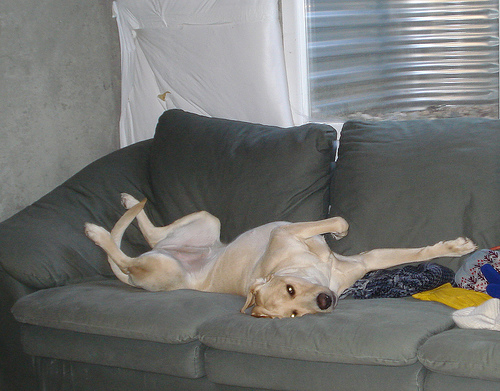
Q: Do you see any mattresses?
A: No, there are no mattresses.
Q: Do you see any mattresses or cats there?
A: No, there are no mattresses or cats.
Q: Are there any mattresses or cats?
A: No, there are no mattresses or cats.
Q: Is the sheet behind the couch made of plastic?
A: Yes, the bed sheet is made of plastic.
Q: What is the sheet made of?
A: The bed sheet is made of plastic.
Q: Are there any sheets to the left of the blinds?
A: Yes, there is a sheet to the left of the blinds.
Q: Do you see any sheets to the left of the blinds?
A: Yes, there is a sheet to the left of the blinds.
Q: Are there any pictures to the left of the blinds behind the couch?
A: No, there is a sheet to the left of the blinds.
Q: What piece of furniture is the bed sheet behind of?
A: The bed sheet is behind the couch.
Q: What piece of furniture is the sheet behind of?
A: The bed sheet is behind the couch.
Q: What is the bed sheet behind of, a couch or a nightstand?
A: The bed sheet is behind a couch.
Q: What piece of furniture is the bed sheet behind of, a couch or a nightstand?
A: The bed sheet is behind a couch.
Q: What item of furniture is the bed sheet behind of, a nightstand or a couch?
A: The bed sheet is behind a couch.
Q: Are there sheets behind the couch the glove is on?
A: Yes, there is a sheet behind the couch.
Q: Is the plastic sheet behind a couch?
A: Yes, the sheet is behind a couch.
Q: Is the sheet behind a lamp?
A: No, the sheet is behind a couch.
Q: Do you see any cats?
A: No, there are no cats.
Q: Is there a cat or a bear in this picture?
A: No, there are no cats or bears.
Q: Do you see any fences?
A: No, there are no fences.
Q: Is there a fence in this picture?
A: No, there are no fences.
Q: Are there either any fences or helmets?
A: No, there are no fences or helmets.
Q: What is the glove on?
A: The glove is on the couch.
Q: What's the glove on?
A: The glove is on the couch.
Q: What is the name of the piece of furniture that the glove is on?
A: The piece of furniture is a couch.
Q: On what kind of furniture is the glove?
A: The glove is on the couch.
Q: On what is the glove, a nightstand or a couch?
A: The glove is on a couch.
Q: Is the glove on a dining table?
A: No, the glove is on the couch.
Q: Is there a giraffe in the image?
A: No, there are no giraffes.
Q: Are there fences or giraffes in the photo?
A: No, there are no giraffes or fences.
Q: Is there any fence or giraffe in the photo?
A: No, there are no giraffes or fences.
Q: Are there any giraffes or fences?
A: No, there are no giraffes or fences.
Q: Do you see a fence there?
A: No, there are no fences.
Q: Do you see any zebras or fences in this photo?
A: No, there are no fences or zebras.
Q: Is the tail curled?
A: Yes, the tail is curled.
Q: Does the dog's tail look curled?
A: Yes, the tail is curled.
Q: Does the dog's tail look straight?
A: No, the tail is curled.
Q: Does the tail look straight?
A: No, the tail is curled.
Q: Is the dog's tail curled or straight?
A: The tail is curled.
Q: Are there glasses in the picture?
A: No, there are no glasses.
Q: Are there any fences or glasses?
A: No, there are no glasses or fences.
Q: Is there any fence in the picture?
A: No, there are no fences.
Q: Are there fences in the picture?
A: No, there are no fences.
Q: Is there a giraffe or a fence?
A: No, there are no fences or giraffes.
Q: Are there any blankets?
A: Yes, there is a blanket.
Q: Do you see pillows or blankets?
A: Yes, there is a blanket.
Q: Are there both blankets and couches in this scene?
A: Yes, there are both a blanket and a couch.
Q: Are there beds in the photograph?
A: No, there are no beds.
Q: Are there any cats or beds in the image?
A: No, there are no beds or cats.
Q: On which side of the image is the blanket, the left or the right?
A: The blanket is on the right of the image.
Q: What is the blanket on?
A: The blanket is on the couch.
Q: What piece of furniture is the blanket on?
A: The blanket is on the couch.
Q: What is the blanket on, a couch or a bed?
A: The blanket is on a couch.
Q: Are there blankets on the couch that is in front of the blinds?
A: Yes, there is a blanket on the couch.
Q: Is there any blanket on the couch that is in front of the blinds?
A: Yes, there is a blanket on the couch.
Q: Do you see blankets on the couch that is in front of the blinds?
A: Yes, there is a blanket on the couch.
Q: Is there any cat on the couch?
A: No, there is a blanket on the couch.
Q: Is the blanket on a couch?
A: Yes, the blanket is on a couch.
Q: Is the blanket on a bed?
A: No, the blanket is on a couch.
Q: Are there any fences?
A: No, there are no fences.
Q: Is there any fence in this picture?
A: No, there are no fences.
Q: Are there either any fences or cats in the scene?
A: No, there are no fences or cats.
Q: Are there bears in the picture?
A: No, there are no bears.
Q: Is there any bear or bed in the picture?
A: No, there are no bears or beds.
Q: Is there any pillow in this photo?
A: Yes, there are pillows.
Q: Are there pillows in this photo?
A: Yes, there are pillows.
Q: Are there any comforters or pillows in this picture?
A: Yes, there are pillows.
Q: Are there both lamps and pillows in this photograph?
A: No, there are pillows but no lamps.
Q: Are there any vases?
A: No, there are no vases.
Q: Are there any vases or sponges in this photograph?
A: No, there are no vases or sponges.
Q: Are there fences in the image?
A: No, there are no fences.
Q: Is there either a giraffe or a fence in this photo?
A: No, there are no fences or giraffes.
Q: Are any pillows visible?
A: Yes, there is a pillow.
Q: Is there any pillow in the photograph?
A: Yes, there is a pillow.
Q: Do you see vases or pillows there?
A: Yes, there is a pillow.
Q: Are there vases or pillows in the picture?
A: Yes, there is a pillow.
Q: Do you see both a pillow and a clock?
A: No, there is a pillow but no clocks.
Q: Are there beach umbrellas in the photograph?
A: No, there are no beach umbrellas.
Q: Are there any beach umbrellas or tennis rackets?
A: No, there are no beach umbrellas or tennis rackets.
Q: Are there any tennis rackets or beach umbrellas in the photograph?
A: No, there are no beach umbrellas or tennis rackets.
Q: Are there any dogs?
A: Yes, there is a dog.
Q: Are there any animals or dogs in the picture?
A: Yes, there is a dog.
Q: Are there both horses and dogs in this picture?
A: No, there is a dog but no horses.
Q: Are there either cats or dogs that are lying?
A: Yes, the dog is lying.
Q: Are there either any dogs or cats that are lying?
A: Yes, the dog is lying.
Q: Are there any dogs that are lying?
A: Yes, there is a dog that is lying.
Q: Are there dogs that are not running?
A: Yes, there is a dog that is lying.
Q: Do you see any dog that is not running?
A: Yes, there is a dog that is lying .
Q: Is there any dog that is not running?
A: Yes, there is a dog that is lying.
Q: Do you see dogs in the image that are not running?
A: Yes, there is a dog that is lying .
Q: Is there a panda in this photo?
A: No, there are no pandas.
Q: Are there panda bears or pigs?
A: No, there are no panda bears or pigs.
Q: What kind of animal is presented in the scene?
A: The animal is a dog.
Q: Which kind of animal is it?
A: The animal is a dog.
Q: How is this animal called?
A: This is a dog.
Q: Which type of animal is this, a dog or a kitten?
A: This is a dog.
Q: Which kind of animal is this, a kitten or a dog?
A: This is a dog.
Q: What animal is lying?
A: The animal is a dog.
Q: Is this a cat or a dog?
A: This is a dog.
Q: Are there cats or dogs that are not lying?
A: No, there is a dog but it is lying.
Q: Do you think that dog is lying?
A: Yes, the dog is lying.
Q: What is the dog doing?
A: The dog is lying.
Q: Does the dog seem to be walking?
A: No, the dog is lying.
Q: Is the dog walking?
A: No, the dog is lying.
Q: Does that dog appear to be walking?
A: No, the dog is lying.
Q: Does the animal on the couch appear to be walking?
A: No, the dog is lying.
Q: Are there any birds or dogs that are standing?
A: No, there is a dog but it is lying.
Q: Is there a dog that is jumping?
A: No, there is a dog but it is lying.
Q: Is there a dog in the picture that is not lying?
A: No, there is a dog but it is lying.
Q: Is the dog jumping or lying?
A: The dog is lying.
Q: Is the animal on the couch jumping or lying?
A: The dog is lying.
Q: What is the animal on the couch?
A: The animal is a dog.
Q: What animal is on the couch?
A: The animal is a dog.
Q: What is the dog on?
A: The dog is on the couch.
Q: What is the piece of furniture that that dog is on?
A: The piece of furniture is a couch.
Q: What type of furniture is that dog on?
A: The dog is on the couch.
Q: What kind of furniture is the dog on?
A: The dog is on the couch.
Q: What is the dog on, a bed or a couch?
A: The dog is on a couch.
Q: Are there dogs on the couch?
A: Yes, there is a dog on the couch.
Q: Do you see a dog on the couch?
A: Yes, there is a dog on the couch.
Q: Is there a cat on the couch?
A: No, there is a dog on the couch.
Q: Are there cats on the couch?
A: No, there is a dog on the couch.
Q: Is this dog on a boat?
A: No, the dog is on the couch.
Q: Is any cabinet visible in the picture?
A: No, there are no cabinets.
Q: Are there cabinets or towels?
A: No, there are no cabinets or towels.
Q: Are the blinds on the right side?
A: Yes, the blinds are on the right of the image.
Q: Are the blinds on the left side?
A: No, the blinds are on the right of the image.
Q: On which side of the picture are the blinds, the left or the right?
A: The blinds are on the right of the image.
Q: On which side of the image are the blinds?
A: The blinds are on the right of the image.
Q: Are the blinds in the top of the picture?
A: Yes, the blinds are in the top of the image.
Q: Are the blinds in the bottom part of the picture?
A: No, the blinds are in the top of the image.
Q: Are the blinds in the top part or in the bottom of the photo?
A: The blinds are in the top of the image.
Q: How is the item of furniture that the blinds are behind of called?
A: The piece of furniture is a couch.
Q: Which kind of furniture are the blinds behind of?
A: The blinds are behind the couch.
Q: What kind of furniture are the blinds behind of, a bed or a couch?
A: The blinds are behind a couch.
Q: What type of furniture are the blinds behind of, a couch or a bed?
A: The blinds are behind a couch.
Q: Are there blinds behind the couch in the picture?
A: Yes, there are blinds behind the couch.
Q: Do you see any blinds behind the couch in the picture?
A: Yes, there are blinds behind the couch.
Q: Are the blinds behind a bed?
A: No, the blinds are behind the couch.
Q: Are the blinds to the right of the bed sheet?
A: Yes, the blinds are to the right of the bed sheet.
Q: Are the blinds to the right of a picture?
A: No, the blinds are to the right of the bed sheet.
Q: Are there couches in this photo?
A: Yes, there is a couch.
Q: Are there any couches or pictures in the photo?
A: Yes, there is a couch.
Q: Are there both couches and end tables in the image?
A: No, there is a couch but no end tables.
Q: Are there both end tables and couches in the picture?
A: No, there is a couch but no end tables.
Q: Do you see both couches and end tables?
A: No, there is a couch but no end tables.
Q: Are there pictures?
A: No, there are no pictures.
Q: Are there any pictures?
A: No, there are no pictures.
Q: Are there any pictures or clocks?
A: No, there are no pictures or clocks.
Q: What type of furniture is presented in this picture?
A: The furniture is a couch.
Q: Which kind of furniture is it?
A: The piece of furniture is a couch.